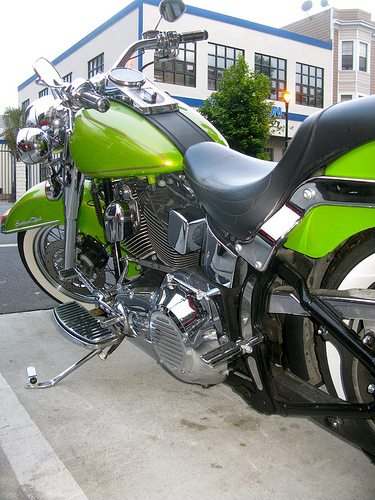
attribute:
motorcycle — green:
[23, 77, 373, 467]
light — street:
[280, 89, 294, 114]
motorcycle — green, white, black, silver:
[2, 1, 370, 464]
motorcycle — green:
[26, 52, 367, 418]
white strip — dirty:
[2, 370, 89, 498]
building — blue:
[14, 1, 333, 212]